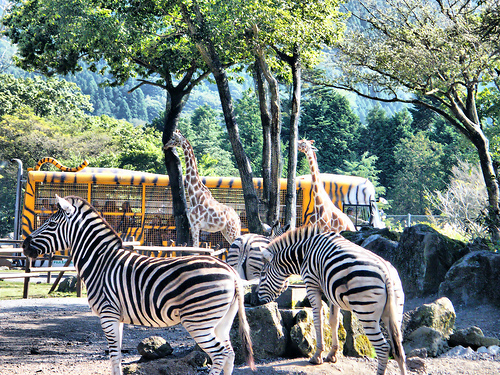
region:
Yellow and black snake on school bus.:
[26, 154, 99, 174]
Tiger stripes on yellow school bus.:
[87, 170, 167, 186]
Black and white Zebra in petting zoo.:
[24, 197, 265, 373]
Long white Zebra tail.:
[381, 264, 420, 373]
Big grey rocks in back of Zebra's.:
[392, 217, 498, 302]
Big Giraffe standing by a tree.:
[154, 127, 251, 248]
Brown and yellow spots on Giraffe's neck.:
[309, 159, 326, 209]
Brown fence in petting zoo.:
[1, 243, 27, 304]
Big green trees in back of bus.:
[354, 120, 452, 177]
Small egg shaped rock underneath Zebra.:
[134, 334, 177, 365]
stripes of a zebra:
[149, 270, 167, 306]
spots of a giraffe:
[191, 184, 207, 213]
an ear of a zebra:
[51, 188, 73, 218]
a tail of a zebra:
[232, 281, 257, 373]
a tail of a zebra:
[384, 272, 410, 372]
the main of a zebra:
[271, 228, 298, 253]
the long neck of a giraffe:
[179, 141, 203, 186]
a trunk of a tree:
[163, 146, 200, 249]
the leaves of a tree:
[91, 13, 136, 48]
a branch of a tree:
[346, 92, 430, 105]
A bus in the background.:
[17, 128, 395, 258]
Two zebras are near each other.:
[27, 186, 420, 371]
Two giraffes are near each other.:
[147, 126, 347, 226]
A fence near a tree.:
[371, 138, 496, 225]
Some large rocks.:
[392, 225, 492, 291]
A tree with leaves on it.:
[20, 2, 270, 242]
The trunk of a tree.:
[210, 70, 265, 235]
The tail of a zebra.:
[370, 267, 430, 369]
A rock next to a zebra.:
[404, 298, 461, 357]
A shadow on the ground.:
[45, 313, 105, 341]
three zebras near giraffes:
[20, 194, 418, 372]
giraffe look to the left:
[18, 186, 263, 373]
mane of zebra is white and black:
[68, 190, 128, 248]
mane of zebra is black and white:
[251, 218, 331, 249]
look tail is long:
[373, 274, 411, 366]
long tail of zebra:
[232, 281, 264, 373]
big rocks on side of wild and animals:
[399, 216, 497, 342]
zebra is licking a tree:
[290, 130, 355, 236]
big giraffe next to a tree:
[157, 122, 248, 247]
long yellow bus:
[16, 145, 391, 250]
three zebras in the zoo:
[16, 192, 411, 366]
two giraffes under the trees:
[134, 113, 358, 229]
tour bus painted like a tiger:
[8, 155, 385, 263]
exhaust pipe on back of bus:
[5, 146, 28, 252]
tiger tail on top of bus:
[24, 135, 95, 195]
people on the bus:
[92, 199, 146, 215]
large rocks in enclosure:
[333, 209, 491, 326]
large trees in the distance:
[1, 94, 483, 199]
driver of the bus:
[340, 198, 375, 228]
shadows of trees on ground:
[14, 303, 267, 361]